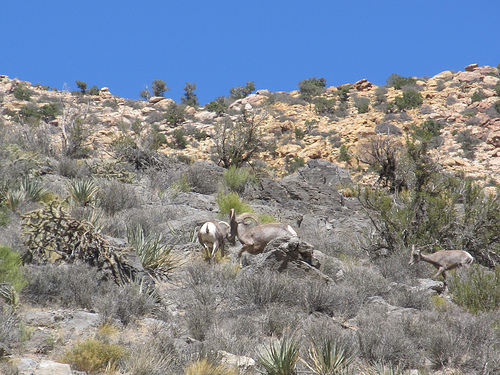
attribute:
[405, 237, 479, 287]
animal horns — wavy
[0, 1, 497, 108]
sky — blue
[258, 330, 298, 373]
leaves — pointy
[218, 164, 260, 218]
bush — green, small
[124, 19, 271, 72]
sky — blue 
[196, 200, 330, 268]
sheep — gray , white 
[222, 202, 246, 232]
horns — curved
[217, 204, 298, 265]
sheep — bighorn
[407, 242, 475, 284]
animal — brown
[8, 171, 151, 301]
tree — old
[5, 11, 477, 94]
sky — blue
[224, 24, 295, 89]
cloud — white 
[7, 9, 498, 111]
sky — blue 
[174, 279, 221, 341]
bush — dry, gray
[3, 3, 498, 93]
sky — blue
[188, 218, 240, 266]
sheep — brown, white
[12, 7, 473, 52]
sky — blue 